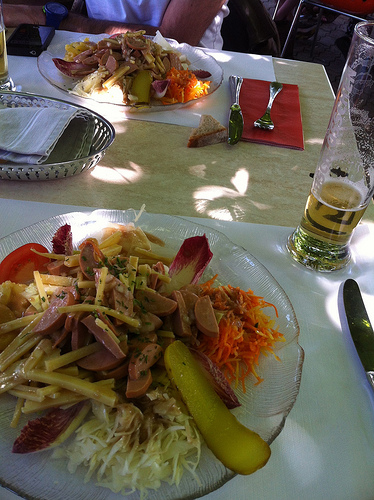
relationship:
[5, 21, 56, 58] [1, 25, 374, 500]
cell phone on table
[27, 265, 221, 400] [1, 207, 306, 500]
hot dog on plate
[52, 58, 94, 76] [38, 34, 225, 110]
tomato on plate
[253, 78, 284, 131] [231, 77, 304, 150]
fork on napkin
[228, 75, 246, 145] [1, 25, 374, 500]
butter knife on table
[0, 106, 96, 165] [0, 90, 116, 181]
napkin in a basket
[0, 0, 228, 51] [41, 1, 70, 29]
person wearing a black watch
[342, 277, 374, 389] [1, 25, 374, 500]
knife on table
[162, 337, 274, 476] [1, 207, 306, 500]
pickle in a bowl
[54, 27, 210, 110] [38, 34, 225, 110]
meat in a bowl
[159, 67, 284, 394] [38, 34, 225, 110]
carrots are on plate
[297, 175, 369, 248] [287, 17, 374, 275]
beer in glass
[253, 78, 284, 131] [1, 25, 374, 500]
fork on table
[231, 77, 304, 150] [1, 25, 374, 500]
napkin on table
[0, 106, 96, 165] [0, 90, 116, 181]
towel in a basket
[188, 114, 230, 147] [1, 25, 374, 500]
bread on table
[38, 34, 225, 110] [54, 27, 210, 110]
plate full of meat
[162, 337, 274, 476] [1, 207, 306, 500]
pickle on plate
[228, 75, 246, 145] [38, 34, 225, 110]
knife near plate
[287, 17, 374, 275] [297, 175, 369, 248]
glass has beer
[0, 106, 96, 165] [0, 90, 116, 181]
napkin in basket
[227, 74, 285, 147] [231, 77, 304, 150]
utensils are on napkin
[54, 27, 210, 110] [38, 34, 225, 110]
meat are on plate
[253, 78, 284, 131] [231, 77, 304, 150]
fork on a napkin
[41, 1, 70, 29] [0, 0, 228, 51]
black watch on person